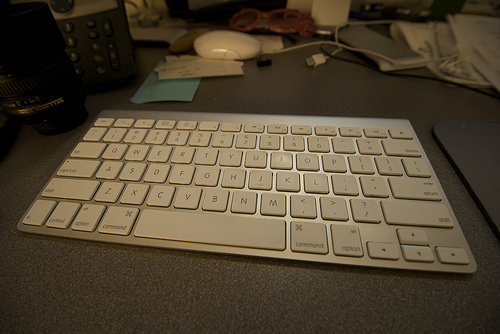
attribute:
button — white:
[289, 219, 329, 255]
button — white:
[328, 222, 362, 258]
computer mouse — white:
[184, 26, 268, 67]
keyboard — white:
[18, 100, 475, 279]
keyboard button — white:
[228, 169, 279, 197]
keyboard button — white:
[101, 205, 138, 236]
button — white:
[115, 153, 149, 182]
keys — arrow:
[367, 240, 400, 260]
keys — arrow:
[399, 227, 427, 244]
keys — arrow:
[436, 245, 467, 264]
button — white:
[364, 237, 398, 262]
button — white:
[130, 210, 293, 262]